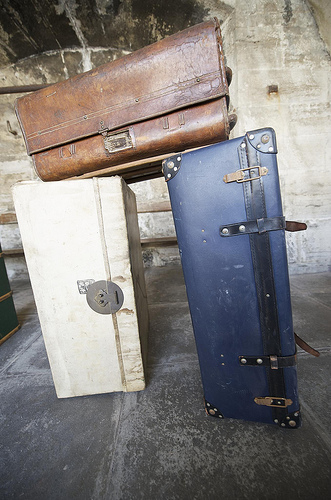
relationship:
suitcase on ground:
[161, 129, 303, 426] [2, 429, 325, 498]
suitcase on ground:
[9, 171, 144, 402] [2, 429, 325, 498]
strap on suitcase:
[105, 133, 134, 157] [13, 18, 237, 183]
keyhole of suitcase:
[98, 290, 109, 309] [9, 171, 144, 402]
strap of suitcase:
[105, 133, 134, 157] [13, 18, 237, 183]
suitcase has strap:
[161, 129, 303, 426] [278, 219, 314, 237]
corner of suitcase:
[245, 129, 278, 156] [161, 129, 303, 426]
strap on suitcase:
[278, 219, 314, 237] [161, 129, 303, 426]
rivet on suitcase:
[204, 282, 247, 318] [161, 129, 303, 426]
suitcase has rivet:
[161, 129, 303, 426] [204, 282, 247, 318]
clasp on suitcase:
[85, 282, 130, 313] [161, 129, 303, 426]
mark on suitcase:
[209, 257, 252, 281] [161, 129, 303, 426]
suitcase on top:
[13, 18, 237, 183] [22, 132, 330, 188]